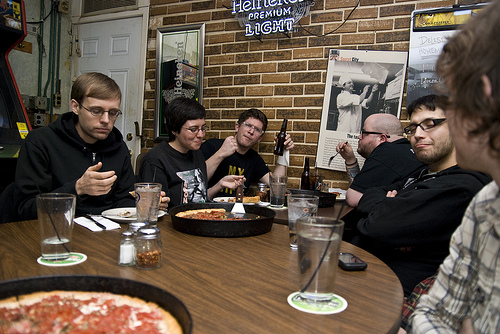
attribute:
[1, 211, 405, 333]
table — large, wooden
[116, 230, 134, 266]
salt shaker — salt shaker, small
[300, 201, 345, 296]
straw — black, long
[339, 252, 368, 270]
cellphone — small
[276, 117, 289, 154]
beer — raised, light, tall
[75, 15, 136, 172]
door — white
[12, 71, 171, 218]
man — sitting, checking, holding, smirking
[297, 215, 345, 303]
glass — tall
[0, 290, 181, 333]
pizza — deep dish, eaten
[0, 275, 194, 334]
pan — black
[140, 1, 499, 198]
wall — brick, brown